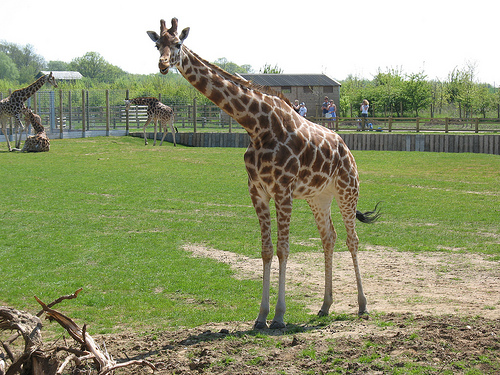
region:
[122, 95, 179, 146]
giraffe crouching down at viewing area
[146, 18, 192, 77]
the head of a giraffe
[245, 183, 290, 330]
front two legs of a giraffe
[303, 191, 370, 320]
back two legs of a giraffe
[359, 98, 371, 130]
person in a white shirt and blue pants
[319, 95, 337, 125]
two people watching giraffes at the zoo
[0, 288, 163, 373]
a pile of wooden braches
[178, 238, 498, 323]
patch of dry dead grass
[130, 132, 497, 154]
wooden picket fence inclosure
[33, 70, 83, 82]
roof of a building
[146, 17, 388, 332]
Brown and white giraffe.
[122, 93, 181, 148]
A giraffe walking around.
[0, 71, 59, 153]
A giraffe in an exhibit.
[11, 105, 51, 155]
A giraffe laying down.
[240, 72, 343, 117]
A gray exhibit building.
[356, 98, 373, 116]
A woman wearing white.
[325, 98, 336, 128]
A woman wearing blue.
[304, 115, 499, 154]
A wooden exhibit fence.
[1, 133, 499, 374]
Green grassy giraffe exhibit.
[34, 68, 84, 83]
A distant building roof.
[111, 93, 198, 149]
giraffe in grassy field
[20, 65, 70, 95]
face of a giraffe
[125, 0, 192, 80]
face of a giraffe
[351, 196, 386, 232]
tail of a giraffe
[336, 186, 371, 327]
leg of a giraffe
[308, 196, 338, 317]
leg of a giraffe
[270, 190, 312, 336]
leg of a giraffe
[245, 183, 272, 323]
leg of a giraffe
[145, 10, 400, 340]
giraffe in a grassy field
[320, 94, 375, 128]
people looking at giraffes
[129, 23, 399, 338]
giraffe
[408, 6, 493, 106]
white clouds in blue sky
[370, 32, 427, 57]
white clouds in blue sky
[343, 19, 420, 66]
white clouds in blue sky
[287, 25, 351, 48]
white clouds in blue sky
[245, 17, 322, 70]
white clouds in blue sky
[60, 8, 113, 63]
white clouds in blue sky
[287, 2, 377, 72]
white clouds in blue sky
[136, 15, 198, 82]
head of the giraffe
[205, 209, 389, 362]
legs of the giraffe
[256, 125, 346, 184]
brown and white giraffe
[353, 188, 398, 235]
tail of the giraffe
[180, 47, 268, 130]
neck of the giraffe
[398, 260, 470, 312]
brown dirt on the ground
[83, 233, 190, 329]
grass on the ground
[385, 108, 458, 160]
fence in the distance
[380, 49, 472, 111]
trees in the distance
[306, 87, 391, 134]
people in the distance